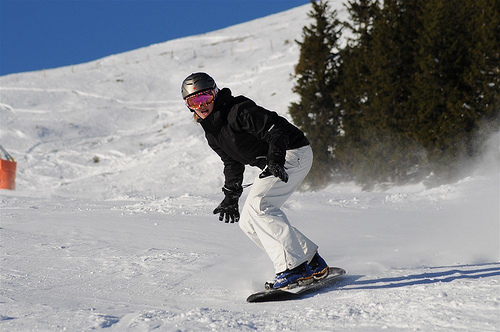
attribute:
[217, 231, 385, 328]
skier — wearing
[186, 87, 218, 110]
goggles — bright , purple tinted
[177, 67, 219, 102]
helmet — grey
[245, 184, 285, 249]
pants — white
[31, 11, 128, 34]
sky — clear, blue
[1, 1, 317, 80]
sky — clear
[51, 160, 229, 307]
snow — white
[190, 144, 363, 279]
pants — white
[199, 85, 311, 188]
jacket — black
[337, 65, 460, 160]
bush — green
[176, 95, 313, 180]
jacket — black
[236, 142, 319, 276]
pants — white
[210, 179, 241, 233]
glove — ON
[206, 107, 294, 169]
jacket — black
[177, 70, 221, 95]
helmet — dark grey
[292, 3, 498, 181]
tree — green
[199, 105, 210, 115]
mouth — open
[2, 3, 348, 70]
sky — dark blue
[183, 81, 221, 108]
goggles — purple tinted